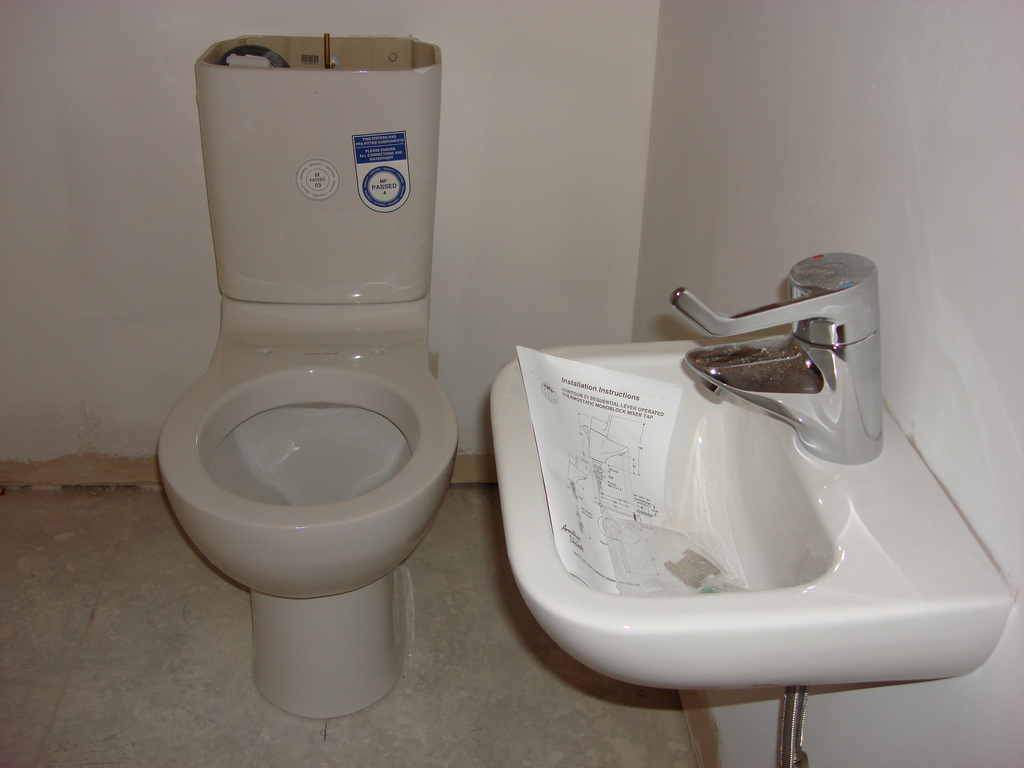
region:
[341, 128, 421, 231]
blue and white label on tank of toilet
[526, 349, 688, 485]
white book of toilet installation instructions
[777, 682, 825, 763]
silver pipe for water under bathroom sink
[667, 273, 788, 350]
silver one handled water faucet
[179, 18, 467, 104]
back of toilet tank with no top on it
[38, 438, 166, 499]
unpainted peach area of wall on left of toilet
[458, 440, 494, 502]
unpainted area to the right of toilet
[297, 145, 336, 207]
white cirular sticker in center of toilet tank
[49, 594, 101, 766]
tan colored line on the floor of the bathroom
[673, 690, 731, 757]
unpainted area under the bathroom sink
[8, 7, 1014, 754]
a small white bathroom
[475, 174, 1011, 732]
small white sink attached to a wall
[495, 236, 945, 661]
a white instruction book in a sink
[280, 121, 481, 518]
a blue and white sticker on a toilet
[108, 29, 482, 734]
a toilet with no toilet seat lid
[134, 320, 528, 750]
the white bowl of a toilet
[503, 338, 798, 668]
a small item in a plastic cover in a sink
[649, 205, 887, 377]
handle of a sink faucet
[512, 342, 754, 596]
instructions papers inside a sink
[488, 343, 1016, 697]
a white sink in a bathroom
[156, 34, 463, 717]
a white toilet in a bathroom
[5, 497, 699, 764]
a dirty white and gray floor in a bathroom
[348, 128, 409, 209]
a white and blue sticker on toilet tank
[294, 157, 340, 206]
a round sticker on the toilet tank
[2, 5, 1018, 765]
white walls in a bathroom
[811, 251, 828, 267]
red indicator on the silver faucet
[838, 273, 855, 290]
blue indicator on the silver faucet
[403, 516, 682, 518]
THIS IS A BATHROOM